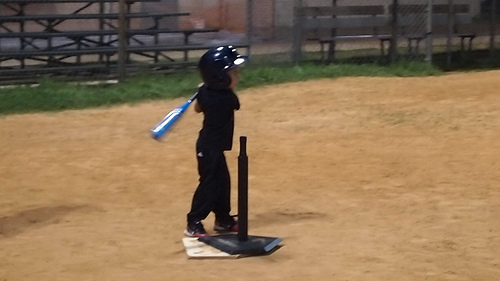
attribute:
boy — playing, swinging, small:
[154, 37, 254, 196]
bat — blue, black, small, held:
[125, 82, 183, 125]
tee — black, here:
[224, 121, 269, 226]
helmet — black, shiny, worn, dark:
[185, 43, 249, 90]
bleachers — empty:
[21, 15, 198, 92]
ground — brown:
[70, 121, 141, 279]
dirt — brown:
[319, 66, 481, 239]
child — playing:
[179, 47, 258, 132]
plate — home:
[165, 208, 292, 280]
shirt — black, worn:
[186, 83, 238, 144]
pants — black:
[186, 152, 279, 269]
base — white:
[208, 238, 248, 268]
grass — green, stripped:
[114, 75, 171, 96]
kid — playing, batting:
[196, 96, 273, 230]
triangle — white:
[188, 141, 207, 164]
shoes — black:
[181, 207, 235, 241]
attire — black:
[177, 72, 248, 244]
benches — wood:
[399, 16, 487, 67]